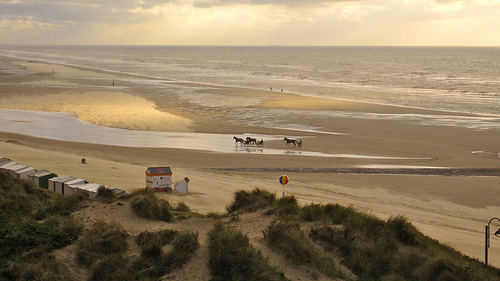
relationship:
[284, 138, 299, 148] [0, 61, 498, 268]
horse on beach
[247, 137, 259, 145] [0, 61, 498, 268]
horse on beach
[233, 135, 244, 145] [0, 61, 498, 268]
horse on beach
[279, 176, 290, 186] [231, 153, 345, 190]
ball in dirt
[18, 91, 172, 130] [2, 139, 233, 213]
sun on sand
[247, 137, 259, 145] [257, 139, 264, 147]
horse pulling man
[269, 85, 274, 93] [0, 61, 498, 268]
person walking on beach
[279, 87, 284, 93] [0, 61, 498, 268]
person walking on beach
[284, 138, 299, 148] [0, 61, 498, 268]
horse walking on beach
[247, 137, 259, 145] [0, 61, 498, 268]
horse walking on beach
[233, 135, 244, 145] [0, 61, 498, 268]
horse walking on beach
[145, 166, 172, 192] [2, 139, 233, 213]
shack on sand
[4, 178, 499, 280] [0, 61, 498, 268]
cliff over beach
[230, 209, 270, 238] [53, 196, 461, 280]
dune on cliff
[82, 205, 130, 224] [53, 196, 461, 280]
dune on cliff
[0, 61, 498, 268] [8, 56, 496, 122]
sand above waterline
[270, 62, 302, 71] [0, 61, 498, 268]
wave breaking on beach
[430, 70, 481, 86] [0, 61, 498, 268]
wave breaking on beach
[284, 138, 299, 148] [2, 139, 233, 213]
horse on sand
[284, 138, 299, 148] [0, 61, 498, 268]
horse on sand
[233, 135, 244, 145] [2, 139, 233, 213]
horse on sand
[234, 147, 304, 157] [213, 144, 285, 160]
reflection on sand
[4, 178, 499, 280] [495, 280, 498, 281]
plants growing on sand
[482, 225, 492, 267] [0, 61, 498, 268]
pole on shore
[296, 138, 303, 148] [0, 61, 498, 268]
buggy on beach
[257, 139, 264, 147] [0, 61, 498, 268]
buggy on beach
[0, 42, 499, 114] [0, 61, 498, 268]
tide on beach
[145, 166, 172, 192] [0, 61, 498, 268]
building on beach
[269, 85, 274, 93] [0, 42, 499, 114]
person walking on water's edge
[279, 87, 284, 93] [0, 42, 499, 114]
person walking on water's edge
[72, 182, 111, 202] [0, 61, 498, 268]
building on beach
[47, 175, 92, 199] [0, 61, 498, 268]
building on beach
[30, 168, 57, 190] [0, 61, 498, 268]
building on beach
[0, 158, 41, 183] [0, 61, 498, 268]
building on beach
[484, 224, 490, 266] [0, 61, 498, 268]
lamp post on beach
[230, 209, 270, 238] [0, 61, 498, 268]
dune beside beach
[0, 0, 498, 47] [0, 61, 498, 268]
sky over beach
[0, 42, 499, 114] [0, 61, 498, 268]
water at beach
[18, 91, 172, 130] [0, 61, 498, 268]
sunshine on beach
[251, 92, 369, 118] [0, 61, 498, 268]
sunshine on beach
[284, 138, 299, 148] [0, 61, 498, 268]
horse walking along shore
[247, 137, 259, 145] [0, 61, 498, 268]
horse walking along shore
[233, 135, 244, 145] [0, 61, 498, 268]
horse walking along shore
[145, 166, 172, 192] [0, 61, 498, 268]
house on beach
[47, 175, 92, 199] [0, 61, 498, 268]
stall on beach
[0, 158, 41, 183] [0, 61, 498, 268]
stall on beach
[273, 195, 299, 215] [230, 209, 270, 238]
shrub on dune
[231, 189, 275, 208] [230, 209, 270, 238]
shrub on dune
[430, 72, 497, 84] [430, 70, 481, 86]
foam on wave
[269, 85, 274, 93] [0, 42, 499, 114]
person swimming in ocean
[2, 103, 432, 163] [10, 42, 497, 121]
water pool from ocean